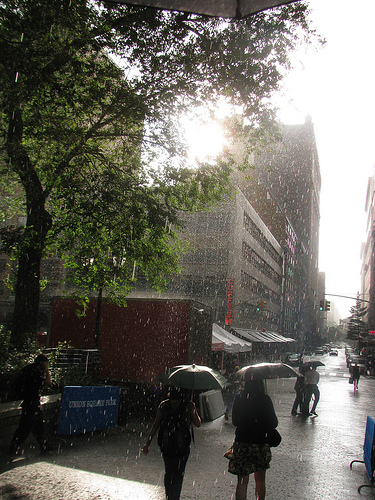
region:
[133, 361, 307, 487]
people holding umbrellas and walking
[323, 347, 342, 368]
street for vehicles to travel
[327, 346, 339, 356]
vehicle on the street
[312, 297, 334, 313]
lights hanging over the street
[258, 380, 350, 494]
sidewalk for pedestrians to travel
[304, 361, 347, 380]
crosswalk for pedestrians to cross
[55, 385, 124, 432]
banner hanging off wall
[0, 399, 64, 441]
stone wall next to plants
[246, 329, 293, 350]
covering over the storefronts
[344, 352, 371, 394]
person on a bike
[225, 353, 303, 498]
woman holds an umbrella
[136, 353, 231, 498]
woman holds an umbrella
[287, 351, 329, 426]
couple hold an umbrella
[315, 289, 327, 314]
traffic light in green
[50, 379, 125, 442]
blue sign with white letters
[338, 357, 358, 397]
man walks on wet street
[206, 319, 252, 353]
the awning color white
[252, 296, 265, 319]
traffic light in green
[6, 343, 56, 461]
man wears black clothes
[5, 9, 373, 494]
A rainy day with the sun still shining.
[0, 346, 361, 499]
Poeple are walking in the rain.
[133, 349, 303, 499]
Two women holding open umbrellas.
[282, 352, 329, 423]
A couple sharing one umbrella.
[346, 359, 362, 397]
The woman walking near the cars has no umbrella.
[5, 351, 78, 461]
A man walks along a stone wall.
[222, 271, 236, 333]
A red neon sign on the building.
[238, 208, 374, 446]
A city street.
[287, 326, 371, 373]
Cars parked on both sides of the street.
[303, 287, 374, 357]
A traffic light at the intersection.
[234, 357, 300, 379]
black umbrella held up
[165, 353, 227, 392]
black umbrella held up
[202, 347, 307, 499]
woman carrying an umbrella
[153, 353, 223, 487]
person carrying an umbrella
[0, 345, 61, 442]
person walking on side walk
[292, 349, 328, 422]
two people walking under an umbrella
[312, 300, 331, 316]
traffic lights hanging down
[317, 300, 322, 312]
green light on traffic fixture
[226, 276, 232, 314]
red sign on building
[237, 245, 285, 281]
line of windows on building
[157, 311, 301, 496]
people are holding umbrellas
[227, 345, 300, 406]
woman has black umbrella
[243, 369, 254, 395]
woman has dark hair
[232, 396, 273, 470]
woman has black coat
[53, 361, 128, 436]
blue sign near people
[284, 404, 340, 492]
grey and wet sidewalk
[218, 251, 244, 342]
red sign on building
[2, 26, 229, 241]
green and leafy tree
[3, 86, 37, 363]
brown tree trunk near blue sign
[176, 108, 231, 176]
sun shining through tree